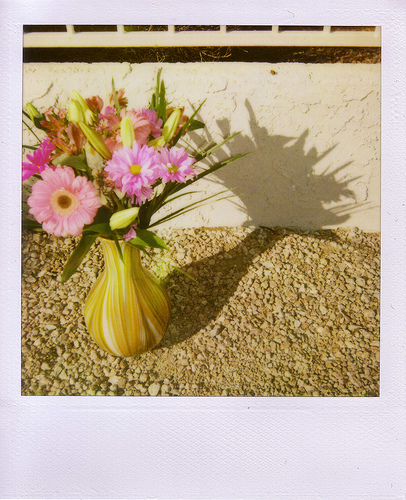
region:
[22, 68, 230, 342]
pink flowers in yellow vase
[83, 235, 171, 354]
yellow stripes on vase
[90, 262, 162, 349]
white patches on yellow vase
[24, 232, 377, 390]
biege gravel under yellow vase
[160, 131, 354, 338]
shadow of vase and flowers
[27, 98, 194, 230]
pink flowers in vase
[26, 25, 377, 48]
white railing above cement wall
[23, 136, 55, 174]
dark pink petals of flower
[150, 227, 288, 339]
shadow of vase on beige gravel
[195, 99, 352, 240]
shadow of flowers on cement wall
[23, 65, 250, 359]
Flower in a pot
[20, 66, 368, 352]
Flower in a pot and its shadow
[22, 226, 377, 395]
Golden brown colored gravel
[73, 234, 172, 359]
Golden brown colored flower pot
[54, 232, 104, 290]
Long, green leaf of a flower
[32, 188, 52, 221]
Pink petals of a flower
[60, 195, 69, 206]
Brown stigma at the center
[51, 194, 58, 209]
Yellow colored collection of anthers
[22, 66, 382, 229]
Rough, white walled background wall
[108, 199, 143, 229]
Closed bud of a flower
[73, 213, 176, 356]
yellow vase holding flowers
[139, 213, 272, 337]
shadow of vase on gravel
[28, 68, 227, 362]
yellow vase full of flowers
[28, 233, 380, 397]
gravel that vase is sitting on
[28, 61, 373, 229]
cement wall behind vase of flowers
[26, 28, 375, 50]
white railing over the top of cement wall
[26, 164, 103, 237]
one pink flower in yellow vase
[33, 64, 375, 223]
cracks in cement wall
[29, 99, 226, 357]
a boquet of flowers in a vase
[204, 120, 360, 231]
a shadow on a wall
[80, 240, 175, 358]
a yellow and white vase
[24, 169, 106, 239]
a pink and yellow flower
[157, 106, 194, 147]
a bud of a flower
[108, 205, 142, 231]
a bud of a flower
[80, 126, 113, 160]
a bud of a flower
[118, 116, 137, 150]
a bud of a flower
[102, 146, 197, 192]
a couple of purple flowers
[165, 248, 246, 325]
a shadow on the ground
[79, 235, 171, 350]
yellow round vase with white sections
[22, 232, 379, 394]
beige colored gravel on ground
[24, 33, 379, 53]
bottom railing of white fence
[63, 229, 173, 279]
green leaves of flowers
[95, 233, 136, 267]
top of yellow vase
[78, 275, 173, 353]
base of yellow vase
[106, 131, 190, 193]
two pink flowers side by side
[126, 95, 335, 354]
shadow vase and flowers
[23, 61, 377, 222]
white cement wall with cracks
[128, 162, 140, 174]
yellow center of pink flower